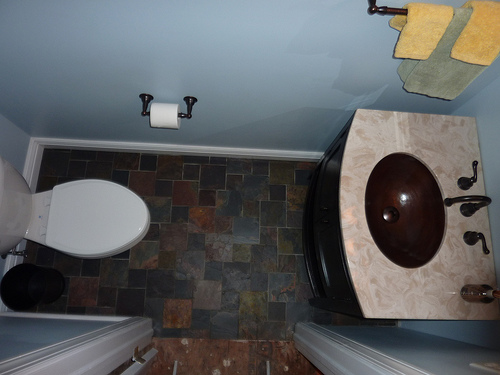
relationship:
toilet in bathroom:
[2, 151, 171, 273] [3, 5, 493, 373]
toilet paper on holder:
[147, 102, 183, 131] [134, 91, 205, 128]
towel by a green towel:
[387, 0, 456, 63] [398, 55, 481, 102]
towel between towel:
[387, 0, 456, 63] [452, 0, 482, 84]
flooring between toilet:
[161, 162, 294, 339] [26, 174, 157, 268]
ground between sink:
[238, 114, 334, 165] [356, 146, 448, 272]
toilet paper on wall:
[150, 102, 184, 127] [1, 0, 492, 157]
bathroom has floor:
[29, 37, 486, 348] [168, 180, 288, 309]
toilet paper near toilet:
[147, 102, 183, 131] [15, 168, 158, 268]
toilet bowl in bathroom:
[0, 153, 152, 262] [3, 5, 493, 373]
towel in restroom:
[387, 0, 456, 63] [4, 3, 498, 373]